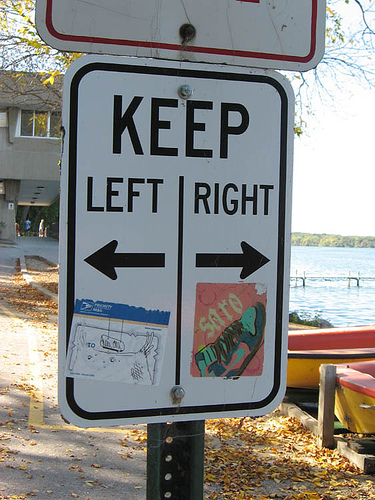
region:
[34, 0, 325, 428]
the signs near the water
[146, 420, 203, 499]
the pole holding the signs up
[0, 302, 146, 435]
the yellow lines on the ground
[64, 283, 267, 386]
the stickers on the sign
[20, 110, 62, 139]
the window in the building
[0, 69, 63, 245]
the building behind the signs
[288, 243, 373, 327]
the body of water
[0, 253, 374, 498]
the leaves on the ground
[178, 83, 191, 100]
the bolt on the sign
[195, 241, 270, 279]
the black arrow on the sign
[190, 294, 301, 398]
red sticker on sign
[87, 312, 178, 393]
white sticker on sign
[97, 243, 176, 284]
black arrow on sign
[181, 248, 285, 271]
black arrow on sign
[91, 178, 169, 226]
black letters on sign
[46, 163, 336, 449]
white sign on post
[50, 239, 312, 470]
metal sign on post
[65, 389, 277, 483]
metal post with sign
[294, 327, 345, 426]
yellow paint on boat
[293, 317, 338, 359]
red paint on boat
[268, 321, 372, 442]
red and yellow boats on lake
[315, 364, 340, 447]
brown wooden pole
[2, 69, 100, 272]
two floors lake house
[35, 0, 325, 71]
red and white signboard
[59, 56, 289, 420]
black and white signboard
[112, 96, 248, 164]
"KEEP" black letters on signboard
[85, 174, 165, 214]
"LEFT" black letters on signboard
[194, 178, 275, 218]
"RIGHT" black letters on signboard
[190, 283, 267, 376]
red and grteen sticker on signboard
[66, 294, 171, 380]
blue and white sticker on signboard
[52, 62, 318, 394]
black and white rectangle sign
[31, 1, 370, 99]
red and white rectangle sign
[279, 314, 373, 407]
red and yellow boat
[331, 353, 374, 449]
plastic boat in the water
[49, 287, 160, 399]
blue and white sticker on sign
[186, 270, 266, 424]
red sticker on sign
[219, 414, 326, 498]
leaves in the sand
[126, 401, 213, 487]
sign on a steel post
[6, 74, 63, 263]
house in the background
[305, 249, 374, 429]
boats on the lake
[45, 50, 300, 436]
The sign is white in color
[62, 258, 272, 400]
Two stickers on the sign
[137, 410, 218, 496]
The sign pole in the foreground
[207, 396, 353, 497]
Fallen leaves on the ground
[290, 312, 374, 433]
Boats in the background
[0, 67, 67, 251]
Building in the background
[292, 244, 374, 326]
A body of water in the background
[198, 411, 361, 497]
Fallen leaves are brown and yellow in color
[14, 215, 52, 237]
People in the background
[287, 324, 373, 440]
The boat is red and yellow in color